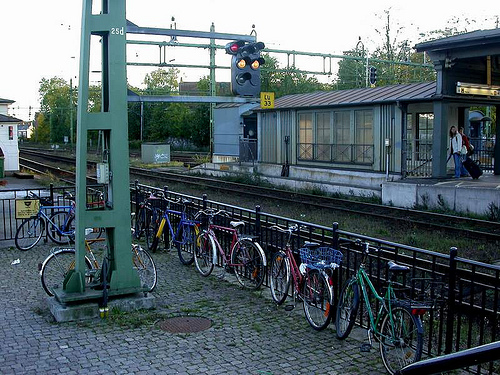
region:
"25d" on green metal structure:
[108, 21, 128, 38]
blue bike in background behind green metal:
[8, 189, 83, 249]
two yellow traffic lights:
[230, 56, 265, 74]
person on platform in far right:
[436, 124, 485, 182]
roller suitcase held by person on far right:
[460, 154, 485, 181]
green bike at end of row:
[335, 231, 425, 368]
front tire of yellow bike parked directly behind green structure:
[133, 243, 156, 290]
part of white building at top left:
[0, 94, 24, 181]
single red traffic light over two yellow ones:
[222, 38, 242, 56]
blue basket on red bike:
[300, 240, 342, 272]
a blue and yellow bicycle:
[149, 188, 202, 266]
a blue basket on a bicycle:
[297, 242, 347, 267]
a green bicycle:
[336, 235, 425, 371]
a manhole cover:
[152, 310, 217, 333]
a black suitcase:
[464, 157, 487, 180]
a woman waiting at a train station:
[443, 120, 484, 182]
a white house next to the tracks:
[1, 92, 22, 178]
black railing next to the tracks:
[124, 179, 498, 360]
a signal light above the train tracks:
[226, 36, 270, 100]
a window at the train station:
[296, 111, 315, 164]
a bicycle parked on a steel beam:
[35, 213, 162, 301]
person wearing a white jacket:
[443, 120, 470, 187]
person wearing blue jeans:
[442, 116, 476, 188]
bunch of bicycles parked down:
[7, 178, 427, 370]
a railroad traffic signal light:
[212, 34, 281, 96]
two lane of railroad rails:
[15, 140, 497, 321]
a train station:
[193, 24, 498, 224]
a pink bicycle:
[260, 219, 340, 330]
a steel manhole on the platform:
[141, 297, 233, 342]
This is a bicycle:
[338, 240, 453, 373]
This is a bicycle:
[270, 221, 340, 329]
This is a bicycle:
[198, 201, 266, 296]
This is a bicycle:
[144, 182, 206, 266]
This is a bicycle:
[25, 227, 164, 310]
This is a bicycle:
[6, 190, 114, 243]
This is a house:
[260, 69, 469, 201]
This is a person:
[439, 115, 481, 185]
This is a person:
[460, 120, 492, 187]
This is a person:
[448, 122, 464, 183]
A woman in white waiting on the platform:
[445, 122, 463, 181]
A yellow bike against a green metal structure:
[37, 219, 151, 306]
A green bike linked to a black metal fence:
[337, 225, 436, 372]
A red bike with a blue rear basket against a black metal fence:
[269, 206, 340, 334]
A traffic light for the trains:
[224, 26, 264, 108]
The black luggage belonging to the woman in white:
[461, 156, 483, 182]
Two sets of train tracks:
[17, 145, 498, 320]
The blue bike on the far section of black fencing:
[8, 184, 82, 251]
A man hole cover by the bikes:
[154, 312, 211, 334]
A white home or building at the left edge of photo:
[0, 94, 22, 171]